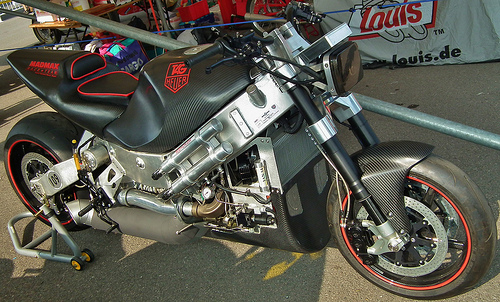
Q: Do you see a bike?
A: Yes, there is a bike.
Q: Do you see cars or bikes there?
A: Yes, there is a bike.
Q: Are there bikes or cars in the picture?
A: Yes, there is a bike.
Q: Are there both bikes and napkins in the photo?
A: No, there is a bike but no napkins.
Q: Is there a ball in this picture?
A: No, there are no balls.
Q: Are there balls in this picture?
A: No, there are no balls.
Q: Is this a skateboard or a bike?
A: This is a bike.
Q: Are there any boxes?
A: No, there are no boxes.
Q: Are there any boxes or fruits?
A: No, there are no boxes or fruits.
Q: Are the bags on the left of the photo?
A: Yes, the bags are on the left of the image.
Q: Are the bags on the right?
A: No, the bags are on the left of the image.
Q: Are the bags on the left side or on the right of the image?
A: The bags are on the left of the image.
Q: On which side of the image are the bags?
A: The bags are on the left of the image.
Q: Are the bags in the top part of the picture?
A: Yes, the bags are in the top of the image.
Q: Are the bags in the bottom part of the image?
A: No, the bags are in the top of the image.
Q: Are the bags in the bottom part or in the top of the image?
A: The bags are in the top of the image.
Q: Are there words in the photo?
A: Yes, there are words.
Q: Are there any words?
A: Yes, there are words.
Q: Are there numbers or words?
A: Yes, there are words.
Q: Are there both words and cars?
A: No, there are words but no cars.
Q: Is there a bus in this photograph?
A: No, there are no buses.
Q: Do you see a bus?
A: No, there are no buses.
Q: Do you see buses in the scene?
A: No, there are no buses.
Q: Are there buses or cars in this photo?
A: No, there are no buses or cars.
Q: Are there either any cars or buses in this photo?
A: No, there are no buses or cars.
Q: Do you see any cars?
A: No, there are no cars.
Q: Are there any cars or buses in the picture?
A: No, there are no cars or buses.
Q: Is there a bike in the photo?
A: Yes, there is a bike.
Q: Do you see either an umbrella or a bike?
A: Yes, there is a bike.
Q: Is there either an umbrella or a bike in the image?
A: Yes, there is a bike.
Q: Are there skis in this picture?
A: No, there are no skis.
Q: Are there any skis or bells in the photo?
A: No, there are no skis or bells.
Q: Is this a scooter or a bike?
A: This is a bike.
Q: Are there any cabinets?
A: No, there are no cabinets.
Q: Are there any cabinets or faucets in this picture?
A: No, there are no cabinets or faucets.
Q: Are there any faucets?
A: No, there are no faucets.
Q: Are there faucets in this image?
A: No, there are no faucets.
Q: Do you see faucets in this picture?
A: No, there are no faucets.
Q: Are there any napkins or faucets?
A: No, there are no faucets or napkins.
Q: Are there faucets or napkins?
A: No, there are no faucets or napkins.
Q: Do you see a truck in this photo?
A: No, there are no trucks.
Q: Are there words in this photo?
A: Yes, there are words.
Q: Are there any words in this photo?
A: Yes, there are words.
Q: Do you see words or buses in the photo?
A: Yes, there are words.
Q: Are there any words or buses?
A: Yes, there are words.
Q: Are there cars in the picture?
A: No, there are no cars.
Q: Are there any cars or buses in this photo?
A: No, there are no cars or buses.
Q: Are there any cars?
A: No, there are no cars.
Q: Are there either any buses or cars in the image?
A: No, there are no cars or buses.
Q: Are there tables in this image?
A: Yes, there is a table.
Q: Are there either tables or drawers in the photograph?
A: Yes, there is a table.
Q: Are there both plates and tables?
A: No, there is a table but no plates.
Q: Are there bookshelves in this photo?
A: No, there are no bookshelves.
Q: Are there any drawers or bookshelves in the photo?
A: No, there are no bookshelves or drawers.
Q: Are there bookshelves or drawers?
A: No, there are no bookshelves or drawers.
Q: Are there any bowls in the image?
A: No, there are no bowls.